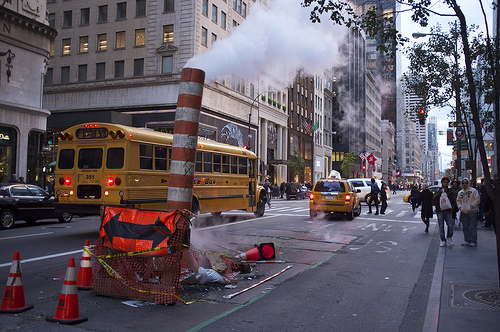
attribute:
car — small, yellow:
[306, 176, 362, 220]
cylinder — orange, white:
[165, 62, 206, 207]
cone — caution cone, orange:
[60, 261, 84, 323]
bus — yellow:
[55, 116, 270, 216]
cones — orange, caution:
[0, 224, 102, 324]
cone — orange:
[53, 255, 93, 323]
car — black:
[0, 175, 72, 224]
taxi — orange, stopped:
[309, 178, 360, 216]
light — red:
[361, 165, 366, 170]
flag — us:
[302, 117, 313, 134]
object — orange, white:
[167, 62, 205, 255]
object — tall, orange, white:
[164, 60, 209, 300]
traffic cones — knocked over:
[234, 239, 276, 260]